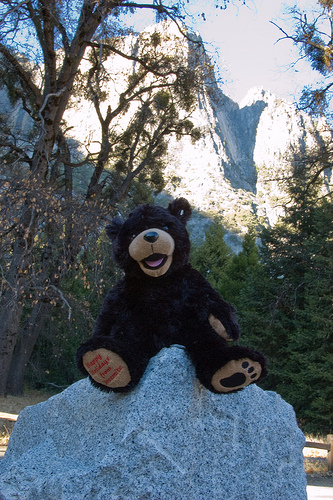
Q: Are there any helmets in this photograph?
A: No, there are no helmets.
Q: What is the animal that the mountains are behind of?
A: The animal is a bear.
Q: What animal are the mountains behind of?
A: The mountains are behind the bear.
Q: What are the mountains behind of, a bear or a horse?
A: The mountains are behind a bear.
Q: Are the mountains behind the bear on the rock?
A: Yes, the mountains are behind the bear.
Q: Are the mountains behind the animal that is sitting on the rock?
A: Yes, the mountains are behind the bear.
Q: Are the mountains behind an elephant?
A: No, the mountains are behind the bear.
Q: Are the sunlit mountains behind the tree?
A: Yes, the mountains are behind the tree.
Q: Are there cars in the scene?
A: No, there are no cars.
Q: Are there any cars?
A: No, there are no cars.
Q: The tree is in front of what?
A: The tree is in front of the mountains.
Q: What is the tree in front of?
A: The tree is in front of the mountains.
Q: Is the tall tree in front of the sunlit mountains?
A: Yes, the tree is in front of the mountains.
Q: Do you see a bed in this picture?
A: No, there are no beds.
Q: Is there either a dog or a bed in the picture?
A: No, there are no beds or dogs.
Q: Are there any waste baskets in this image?
A: No, there are no waste baskets.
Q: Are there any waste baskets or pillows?
A: No, there are no waste baskets or pillows.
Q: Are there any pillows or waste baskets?
A: No, there are no waste baskets or pillows.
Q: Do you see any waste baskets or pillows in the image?
A: No, there are no waste baskets or pillows.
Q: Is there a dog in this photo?
A: No, there are no dogs.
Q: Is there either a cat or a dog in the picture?
A: No, there are no dogs or cats.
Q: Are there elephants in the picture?
A: No, there are no elephants.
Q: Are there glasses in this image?
A: No, there are no glasses.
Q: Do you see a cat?
A: No, there are no cats.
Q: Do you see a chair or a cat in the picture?
A: No, there are no cats or chairs.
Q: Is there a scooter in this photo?
A: No, there are no scooters.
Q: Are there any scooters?
A: No, there are no scooters.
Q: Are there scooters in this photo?
A: No, there are no scooters.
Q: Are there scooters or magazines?
A: No, there are no scooters or magazines.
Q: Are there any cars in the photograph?
A: No, there are no cars.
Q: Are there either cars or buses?
A: No, there are no cars or buses.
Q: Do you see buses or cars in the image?
A: No, there are no cars or buses.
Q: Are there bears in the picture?
A: Yes, there is a bear.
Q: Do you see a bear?
A: Yes, there is a bear.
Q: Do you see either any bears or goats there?
A: Yes, there is a bear.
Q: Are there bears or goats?
A: Yes, there is a bear.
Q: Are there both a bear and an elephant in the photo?
A: No, there is a bear but no elephants.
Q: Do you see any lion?
A: No, there are no lions.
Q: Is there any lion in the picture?
A: No, there are no lions.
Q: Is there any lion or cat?
A: No, there are no lions or cats.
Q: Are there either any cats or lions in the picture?
A: No, there are no lions or cats.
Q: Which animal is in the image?
A: The animal is a bear.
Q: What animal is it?
A: The animal is a bear.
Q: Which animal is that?
A: This is a bear.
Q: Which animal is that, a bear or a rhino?
A: This is a bear.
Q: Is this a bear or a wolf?
A: This is a bear.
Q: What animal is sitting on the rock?
A: The bear is sitting on the rock.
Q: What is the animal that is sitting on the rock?
A: The animal is a bear.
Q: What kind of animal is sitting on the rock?
A: The animal is a bear.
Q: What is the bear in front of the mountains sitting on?
A: The bear is sitting on the rock.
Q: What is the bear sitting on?
A: The bear is sitting on the rock.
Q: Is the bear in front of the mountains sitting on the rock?
A: Yes, the bear is sitting on the rock.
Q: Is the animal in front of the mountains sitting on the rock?
A: Yes, the bear is sitting on the rock.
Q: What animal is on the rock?
A: The bear is on the rock.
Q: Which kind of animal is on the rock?
A: The animal is a bear.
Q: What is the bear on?
A: The bear is on the rock.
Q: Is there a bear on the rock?
A: Yes, there is a bear on the rock.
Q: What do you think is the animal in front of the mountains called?
A: The animal is a bear.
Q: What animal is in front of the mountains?
A: The animal is a bear.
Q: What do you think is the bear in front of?
A: The bear is in front of the mountains.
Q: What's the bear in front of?
A: The bear is in front of the mountains.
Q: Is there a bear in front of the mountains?
A: Yes, there is a bear in front of the mountains.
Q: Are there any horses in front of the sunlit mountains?
A: No, there is a bear in front of the mountains.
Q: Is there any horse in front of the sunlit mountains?
A: No, there is a bear in front of the mountains.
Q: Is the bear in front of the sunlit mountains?
A: Yes, the bear is in front of the mountains.